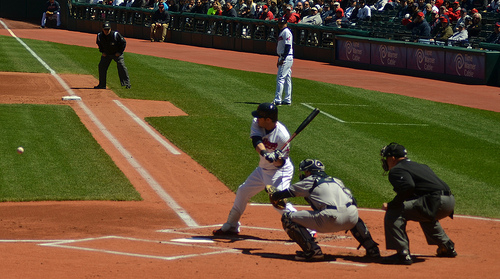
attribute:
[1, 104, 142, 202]
grass — green, turf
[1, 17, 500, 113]
dirt — brown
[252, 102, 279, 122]
helmet — black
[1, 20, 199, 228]
line — white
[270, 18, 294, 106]
man — standing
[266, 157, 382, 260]
catcher — croutching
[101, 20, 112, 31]
hat — black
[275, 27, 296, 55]
shirt — white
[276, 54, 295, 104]
pants — white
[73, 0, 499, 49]
crowd — large, big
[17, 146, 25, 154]
baseball — airborne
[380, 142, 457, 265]
umpire — watching, croutching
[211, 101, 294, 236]
batter — readying, waiting, ready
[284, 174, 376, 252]
uniform — grey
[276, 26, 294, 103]
uniform — white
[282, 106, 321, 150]
bat — black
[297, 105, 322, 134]
tip — black